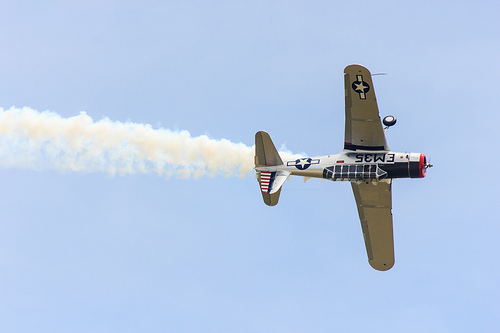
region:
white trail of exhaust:
[3, 105, 246, 180]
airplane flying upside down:
[250, 55, 441, 275]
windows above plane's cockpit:
[325, 165, 385, 180]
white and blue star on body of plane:
[285, 155, 315, 170]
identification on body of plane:
[351, 147, 396, 162]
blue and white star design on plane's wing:
[350, 67, 368, 102]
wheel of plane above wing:
[380, 108, 396, 134]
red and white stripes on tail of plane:
[257, 170, 267, 195]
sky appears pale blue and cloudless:
[70, 10, 330, 105]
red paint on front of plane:
[418, 153, 426, 174]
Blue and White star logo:
[350, 70, 372, 108]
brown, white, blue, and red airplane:
[243, 40, 431, 293]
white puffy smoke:
[3, 88, 248, 210]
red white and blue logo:
[253, 167, 278, 199]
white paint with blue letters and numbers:
[352, 149, 405, 163]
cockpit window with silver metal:
[320, 163, 392, 184]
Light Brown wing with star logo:
[341, 61, 389, 151]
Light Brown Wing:
[346, 181, 406, 276]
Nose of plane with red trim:
[416, 148, 440, 188]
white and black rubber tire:
[383, 105, 398, 136]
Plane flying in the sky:
[237, 52, 433, 274]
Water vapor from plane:
[0, 105, 320, 185]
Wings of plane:
[335, 50, 400, 270]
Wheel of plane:
[383, 107, 398, 127]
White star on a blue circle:
[290, 150, 310, 165]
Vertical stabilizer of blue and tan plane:
[245, 125, 280, 205]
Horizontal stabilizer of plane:
[246, 125, 285, 207]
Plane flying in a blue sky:
[12, 11, 497, 316]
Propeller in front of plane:
[420, 150, 435, 176]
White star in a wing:
[345, 71, 372, 98]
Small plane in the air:
[246, 60, 437, 274]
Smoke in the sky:
[3, 102, 255, 192]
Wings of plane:
[340, 60, 402, 270]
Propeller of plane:
[423, 151, 434, 176]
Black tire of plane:
[384, 112, 398, 126]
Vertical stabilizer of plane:
[267, 164, 295, 196]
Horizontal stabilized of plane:
[248, 129, 280, 212]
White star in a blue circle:
[295, 155, 312, 169]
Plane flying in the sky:
[0, 2, 496, 322]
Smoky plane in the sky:
[1, 1, 493, 328]